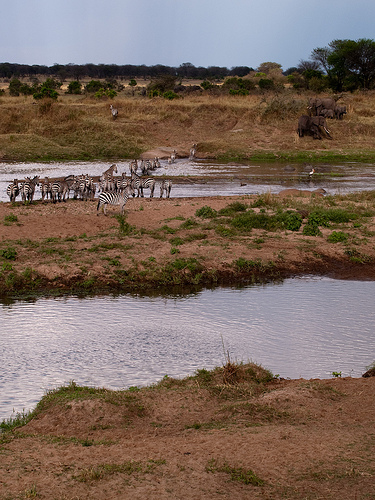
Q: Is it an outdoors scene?
A: Yes, it is outdoors.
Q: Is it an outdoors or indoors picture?
A: It is outdoors.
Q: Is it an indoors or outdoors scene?
A: It is outdoors.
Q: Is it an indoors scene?
A: No, it is outdoors.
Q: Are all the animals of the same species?
A: No, there are both zebras and birds.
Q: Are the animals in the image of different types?
A: Yes, they are zebras and birds.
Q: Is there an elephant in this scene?
A: Yes, there is an elephant.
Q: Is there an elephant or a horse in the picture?
A: Yes, there is an elephant.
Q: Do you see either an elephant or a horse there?
A: Yes, there is an elephant.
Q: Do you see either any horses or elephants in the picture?
A: Yes, there is an elephant.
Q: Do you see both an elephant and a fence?
A: No, there is an elephant but no fences.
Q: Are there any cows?
A: No, there are no cows.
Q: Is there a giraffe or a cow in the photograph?
A: No, there are no cows or giraffes.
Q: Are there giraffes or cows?
A: No, there are no cows or giraffes.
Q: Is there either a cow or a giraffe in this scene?
A: No, there are no cows or giraffes.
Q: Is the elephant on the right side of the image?
A: Yes, the elephant is on the right of the image.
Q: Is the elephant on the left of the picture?
A: No, the elephant is on the right of the image.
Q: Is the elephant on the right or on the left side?
A: The elephant is on the right of the image.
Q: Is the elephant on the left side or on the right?
A: The elephant is on the right of the image.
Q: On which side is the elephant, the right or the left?
A: The elephant is on the right of the image.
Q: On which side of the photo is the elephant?
A: The elephant is on the right of the image.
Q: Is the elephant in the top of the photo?
A: Yes, the elephant is in the top of the image.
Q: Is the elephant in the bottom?
A: No, the elephant is in the top of the image.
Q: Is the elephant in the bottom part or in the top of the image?
A: The elephant is in the top of the image.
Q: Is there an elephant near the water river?
A: Yes, there is an elephant near the river.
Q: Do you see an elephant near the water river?
A: Yes, there is an elephant near the river.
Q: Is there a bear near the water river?
A: No, there is an elephant near the river.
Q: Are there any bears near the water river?
A: No, there is an elephant near the river.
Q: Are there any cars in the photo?
A: No, there are no cars.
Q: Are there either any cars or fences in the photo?
A: No, there are no cars or fences.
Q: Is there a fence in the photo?
A: No, there are no fences.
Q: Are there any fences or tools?
A: No, there are no fences or tools.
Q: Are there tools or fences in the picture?
A: No, there are no fences or tools.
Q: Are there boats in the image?
A: No, there are no boats.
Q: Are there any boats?
A: No, there are no boats.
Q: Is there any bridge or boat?
A: No, there are no boats or bridges.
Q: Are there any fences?
A: No, there are no fences.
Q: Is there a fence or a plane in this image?
A: No, there are no fences or airplanes.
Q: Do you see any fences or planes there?
A: No, there are no fences or planes.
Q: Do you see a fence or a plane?
A: No, there are no fences or airplanes.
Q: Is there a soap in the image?
A: No, there are no soaps.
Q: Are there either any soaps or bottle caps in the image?
A: No, there are no soaps or bottle caps.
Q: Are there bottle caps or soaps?
A: No, there are no soaps or bottle caps.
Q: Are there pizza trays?
A: No, there are no pizza trays.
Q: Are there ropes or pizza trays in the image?
A: No, there are no pizza trays or ropes.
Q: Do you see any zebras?
A: Yes, there is a zebra.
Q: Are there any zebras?
A: Yes, there is a zebra.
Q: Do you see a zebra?
A: Yes, there is a zebra.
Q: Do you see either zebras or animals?
A: Yes, there is a zebra.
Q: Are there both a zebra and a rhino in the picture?
A: No, there is a zebra but no rhinos.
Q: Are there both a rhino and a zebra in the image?
A: No, there is a zebra but no rhinos.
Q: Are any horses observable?
A: No, there are no horses.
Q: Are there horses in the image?
A: No, there are no horses.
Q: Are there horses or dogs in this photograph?
A: No, there are no horses or dogs.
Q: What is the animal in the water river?
A: The animal is a zebra.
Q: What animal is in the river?
A: The animal is a zebra.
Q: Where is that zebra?
A: The zebra is in the river.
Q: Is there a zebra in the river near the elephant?
A: Yes, there is a zebra in the river.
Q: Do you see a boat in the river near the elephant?
A: No, there is a zebra in the river.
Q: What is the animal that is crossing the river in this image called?
A: The animal is a zebra.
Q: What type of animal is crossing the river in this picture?
A: The animal is a zebra.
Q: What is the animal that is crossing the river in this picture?
A: The animal is a zebra.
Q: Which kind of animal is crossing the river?
A: The animal is a zebra.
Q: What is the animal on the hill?
A: The animal is a zebra.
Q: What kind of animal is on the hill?
A: The animal is a zebra.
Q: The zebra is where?
A: The zebra is on the hill.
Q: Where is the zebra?
A: The zebra is on the hill.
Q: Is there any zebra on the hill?
A: Yes, there is a zebra on the hill.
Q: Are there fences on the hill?
A: No, there is a zebra on the hill.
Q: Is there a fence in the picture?
A: No, there are no fences.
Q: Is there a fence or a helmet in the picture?
A: No, there are no fences or helmets.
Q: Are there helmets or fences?
A: No, there are no fences or helmets.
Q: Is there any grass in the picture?
A: Yes, there is grass.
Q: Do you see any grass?
A: Yes, there is grass.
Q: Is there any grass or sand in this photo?
A: Yes, there is grass.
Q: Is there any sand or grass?
A: Yes, there is grass.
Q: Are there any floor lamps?
A: No, there are no floor lamps.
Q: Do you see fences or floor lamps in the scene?
A: No, there are no floor lamps or fences.